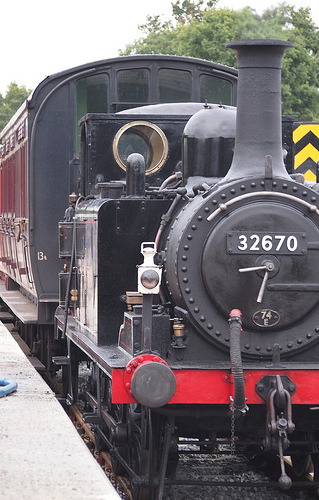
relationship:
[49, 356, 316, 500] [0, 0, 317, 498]
track in photo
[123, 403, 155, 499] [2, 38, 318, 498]
wheel on train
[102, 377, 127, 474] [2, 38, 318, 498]
wheel on train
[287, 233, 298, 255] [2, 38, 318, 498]
number on train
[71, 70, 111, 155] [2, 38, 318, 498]
window on train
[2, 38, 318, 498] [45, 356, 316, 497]
train on track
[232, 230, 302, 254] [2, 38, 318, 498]
number on train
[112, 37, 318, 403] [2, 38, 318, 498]
front on train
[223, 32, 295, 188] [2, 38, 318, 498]
smoke stack on train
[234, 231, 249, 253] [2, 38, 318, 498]
number on train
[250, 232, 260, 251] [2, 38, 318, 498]
number on train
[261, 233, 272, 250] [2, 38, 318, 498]
number on train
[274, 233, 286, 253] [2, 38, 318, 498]
number on train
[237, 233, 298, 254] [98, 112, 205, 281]
number on train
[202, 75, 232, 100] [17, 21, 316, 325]
window on train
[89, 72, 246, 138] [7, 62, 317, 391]
windows on train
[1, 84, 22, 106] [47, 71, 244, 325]
trees behind train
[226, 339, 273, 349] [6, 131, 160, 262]
black hose on train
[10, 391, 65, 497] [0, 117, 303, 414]
platform beside train